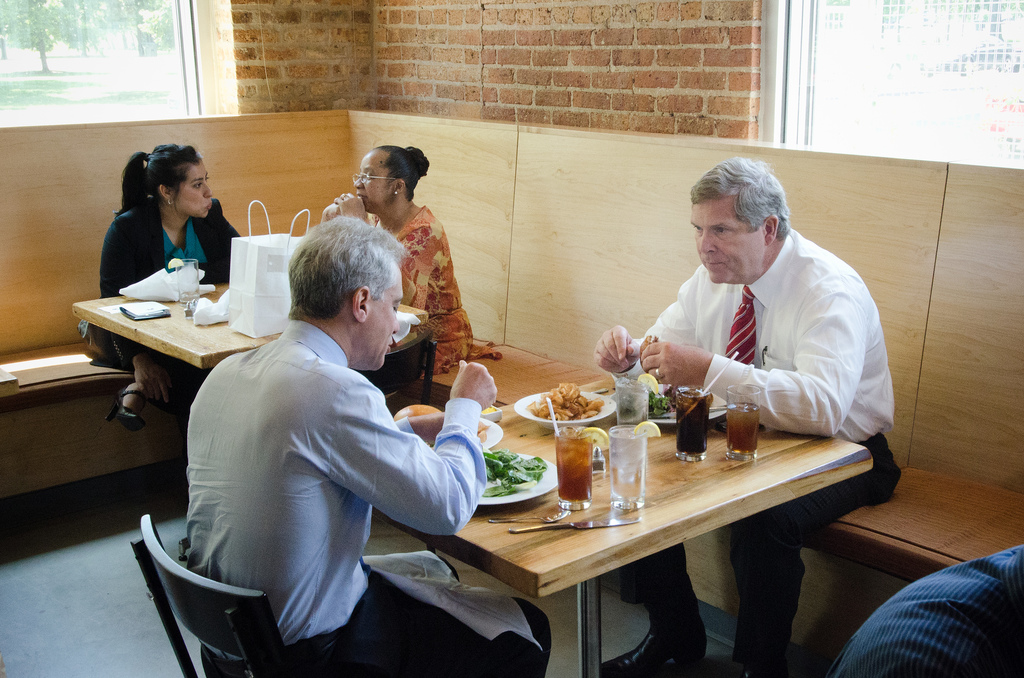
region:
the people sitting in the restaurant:
[1, 2, 1019, 670]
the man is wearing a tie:
[598, 157, 900, 676]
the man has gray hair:
[595, 151, 902, 670]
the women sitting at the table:
[71, 141, 473, 490]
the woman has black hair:
[80, 146, 240, 426]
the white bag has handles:
[226, 200, 313, 341]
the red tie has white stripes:
[727, 288, 759, 371]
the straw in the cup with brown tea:
[544, 392, 609, 510]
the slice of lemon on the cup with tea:
[541, 394, 606, 506]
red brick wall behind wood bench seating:
[220, 4, 771, 129]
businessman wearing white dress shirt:
[603, 165, 897, 491]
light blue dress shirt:
[185, 317, 499, 649]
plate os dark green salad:
[474, 426, 554, 502]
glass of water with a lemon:
[613, 399, 661, 514]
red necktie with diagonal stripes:
[727, 282, 760, 399]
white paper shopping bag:
[226, 199, 316, 329]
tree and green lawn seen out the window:
[3, 4, 197, 115]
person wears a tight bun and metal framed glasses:
[351, 142, 437, 213]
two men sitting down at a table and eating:
[184, 148, 902, 676]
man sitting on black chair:
[130, 211, 557, 674]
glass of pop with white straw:
[668, 345, 741, 460]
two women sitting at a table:
[81, 142, 502, 425]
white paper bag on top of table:
[226, 193, 312, 340]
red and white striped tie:
[721, 277, 763, 366]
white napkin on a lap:
[358, 547, 543, 653]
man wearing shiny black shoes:
[592, 154, 903, 676]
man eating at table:
[667, 155, 861, 371]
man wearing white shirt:
[653, 160, 879, 383]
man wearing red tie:
[669, 153, 911, 384]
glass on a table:
[598, 413, 660, 522]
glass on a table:
[533, 392, 610, 513]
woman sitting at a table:
[95, 128, 228, 242]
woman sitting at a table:
[340, 128, 429, 209]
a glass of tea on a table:
[552, 423, 598, 515]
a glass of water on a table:
[603, 420, 652, 510]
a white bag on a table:
[229, 201, 313, 341]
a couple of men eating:
[141, 166, 894, 672]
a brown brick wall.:
[380, 2, 750, 135]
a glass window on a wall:
[11, 3, 236, 127]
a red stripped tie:
[728, 289, 763, 365]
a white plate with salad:
[470, 445, 554, 510]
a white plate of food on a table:
[520, 378, 615, 435]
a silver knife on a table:
[508, 514, 636, 535]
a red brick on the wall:
[509, 16, 541, 45]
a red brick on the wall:
[418, 34, 456, 77]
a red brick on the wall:
[640, 95, 683, 121]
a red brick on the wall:
[275, 42, 298, 62]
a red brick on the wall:
[438, 77, 470, 100]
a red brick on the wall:
[526, 37, 578, 98]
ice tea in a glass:
[557, 432, 595, 521]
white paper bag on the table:
[229, 199, 315, 336]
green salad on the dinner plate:
[472, 445, 543, 496]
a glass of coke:
[674, 384, 710, 458]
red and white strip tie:
[727, 289, 759, 362]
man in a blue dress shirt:
[182, 213, 550, 672]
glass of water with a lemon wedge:
[607, 415, 659, 510]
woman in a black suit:
[90, 143, 247, 426]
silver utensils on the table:
[482, 510, 632, 536]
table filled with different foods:
[386, 378, 878, 673]